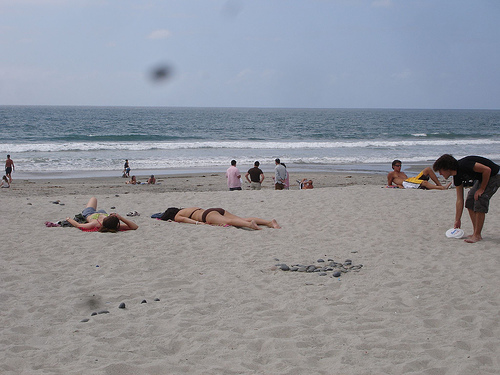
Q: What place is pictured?
A: It is a beach.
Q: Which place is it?
A: It is a beach.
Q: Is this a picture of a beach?
A: Yes, it is showing a beach.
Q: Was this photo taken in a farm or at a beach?
A: It was taken at a beach.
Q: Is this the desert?
A: No, it is the beach.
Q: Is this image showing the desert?
A: No, the picture is showing the beach.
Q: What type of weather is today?
A: It is clear.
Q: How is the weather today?
A: It is clear.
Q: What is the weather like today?
A: It is clear.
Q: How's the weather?
A: It is clear.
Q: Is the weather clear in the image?
A: Yes, it is clear.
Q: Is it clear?
A: Yes, it is clear.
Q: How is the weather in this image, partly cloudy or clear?
A: It is clear.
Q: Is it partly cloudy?
A: No, it is clear.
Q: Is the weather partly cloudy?
A: No, it is clear.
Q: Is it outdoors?
A: Yes, it is outdoors.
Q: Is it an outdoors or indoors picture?
A: It is outdoors.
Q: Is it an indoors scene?
A: No, it is outdoors.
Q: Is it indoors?
A: No, it is outdoors.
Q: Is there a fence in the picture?
A: No, there are no fences.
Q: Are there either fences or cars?
A: No, there are no fences or cars.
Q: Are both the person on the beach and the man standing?
A: Yes, both the person and the man are standing.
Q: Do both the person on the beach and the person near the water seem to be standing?
A: Yes, both the person and the man are standing.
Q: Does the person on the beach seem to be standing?
A: Yes, the person is standing.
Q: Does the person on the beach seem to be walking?
A: No, the person is standing.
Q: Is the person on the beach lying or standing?
A: The person is standing.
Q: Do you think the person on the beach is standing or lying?
A: The person is standing.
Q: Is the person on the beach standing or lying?
A: The person is standing.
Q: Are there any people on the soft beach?
A: Yes, there is a person on the beach.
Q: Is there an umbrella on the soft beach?
A: No, there is a person on the beach.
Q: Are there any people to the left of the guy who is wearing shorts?
A: Yes, there is a person to the left of the guy.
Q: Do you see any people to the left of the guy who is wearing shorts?
A: Yes, there is a person to the left of the guy.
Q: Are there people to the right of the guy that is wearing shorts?
A: No, the person is to the left of the guy.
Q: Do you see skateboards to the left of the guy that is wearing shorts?
A: No, there is a person to the left of the guy.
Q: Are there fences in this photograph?
A: No, there are no fences.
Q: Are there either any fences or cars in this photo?
A: No, there are no fences or cars.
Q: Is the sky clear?
A: Yes, the sky is clear.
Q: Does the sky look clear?
A: Yes, the sky is clear.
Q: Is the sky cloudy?
A: No, the sky is clear.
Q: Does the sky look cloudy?
A: No, the sky is clear.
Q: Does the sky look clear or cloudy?
A: The sky is clear.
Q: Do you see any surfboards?
A: No, there are no surfboards.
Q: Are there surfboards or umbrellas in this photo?
A: No, there are no surfboards or umbrellas.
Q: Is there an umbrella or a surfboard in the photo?
A: No, there are no surfboards or umbrellas.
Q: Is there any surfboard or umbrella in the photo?
A: No, there are no surfboards or umbrellas.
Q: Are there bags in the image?
A: No, there are no bags.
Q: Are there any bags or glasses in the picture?
A: No, there are no bags or glasses.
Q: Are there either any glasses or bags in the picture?
A: No, there are no bags or glasses.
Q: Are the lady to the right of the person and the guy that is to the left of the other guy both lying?
A: Yes, both the lady and the guy are lying.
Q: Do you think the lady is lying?
A: Yes, the lady is lying.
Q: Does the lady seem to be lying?
A: Yes, the lady is lying.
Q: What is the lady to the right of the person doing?
A: The lady is lying.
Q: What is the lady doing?
A: The lady is lying.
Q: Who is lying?
A: The lady is lying.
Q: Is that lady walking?
A: No, the lady is lying.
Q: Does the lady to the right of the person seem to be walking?
A: No, the lady is lying.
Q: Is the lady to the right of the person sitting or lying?
A: The lady is lying.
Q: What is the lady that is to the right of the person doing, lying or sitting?
A: The lady is lying.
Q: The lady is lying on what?
A: The lady is lying on the beach.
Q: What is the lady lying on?
A: The lady is lying on the beach.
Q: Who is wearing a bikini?
A: The lady is wearing a bikini.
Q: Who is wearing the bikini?
A: The lady is wearing a bikini.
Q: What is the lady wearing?
A: The lady is wearing a bikini.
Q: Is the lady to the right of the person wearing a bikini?
A: Yes, the lady is wearing a bikini.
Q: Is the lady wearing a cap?
A: No, the lady is wearing a bikini.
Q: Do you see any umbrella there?
A: No, there are no umbrellas.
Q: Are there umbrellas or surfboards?
A: No, there are no umbrellas or surfboards.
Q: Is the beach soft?
A: Yes, the beach is soft.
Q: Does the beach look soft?
A: Yes, the beach is soft.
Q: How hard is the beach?
A: The beach is soft.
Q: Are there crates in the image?
A: No, there are no crates.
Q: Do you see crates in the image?
A: No, there are no crates.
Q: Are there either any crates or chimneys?
A: No, there are no crates or chimneys.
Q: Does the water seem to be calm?
A: Yes, the water is calm.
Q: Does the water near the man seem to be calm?
A: Yes, the water is calm.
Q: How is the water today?
A: The water is calm.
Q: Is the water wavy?
A: No, the water is calm.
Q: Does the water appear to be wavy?
A: No, the water is calm.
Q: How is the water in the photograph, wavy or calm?
A: The water is calm.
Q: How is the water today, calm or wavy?
A: The water is calm.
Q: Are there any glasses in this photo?
A: No, there are no glasses.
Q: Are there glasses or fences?
A: No, there are no glasses or fences.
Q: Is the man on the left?
A: Yes, the man is on the left of the image.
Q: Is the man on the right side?
A: No, the man is on the left of the image.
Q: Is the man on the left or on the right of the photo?
A: The man is on the left of the image.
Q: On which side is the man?
A: The man is on the left of the image.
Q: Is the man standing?
A: Yes, the man is standing.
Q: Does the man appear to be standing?
A: Yes, the man is standing.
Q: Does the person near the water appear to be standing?
A: Yes, the man is standing.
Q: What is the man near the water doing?
A: The man is standing.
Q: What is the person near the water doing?
A: The man is standing.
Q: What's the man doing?
A: The man is standing.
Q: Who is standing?
A: The man is standing.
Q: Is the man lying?
A: No, the man is standing.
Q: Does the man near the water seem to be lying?
A: No, the man is standing.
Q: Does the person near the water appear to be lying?
A: No, the man is standing.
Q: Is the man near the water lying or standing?
A: The man is standing.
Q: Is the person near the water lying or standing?
A: The man is standing.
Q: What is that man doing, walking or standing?
A: The man is standing.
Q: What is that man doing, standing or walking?
A: The man is standing.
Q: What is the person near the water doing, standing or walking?
A: The man is standing.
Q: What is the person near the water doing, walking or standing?
A: The man is standing.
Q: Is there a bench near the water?
A: No, there is a man near the water.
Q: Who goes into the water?
A: The man goes into the water.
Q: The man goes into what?
A: The man goes into the water.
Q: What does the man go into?
A: The man goes into the water.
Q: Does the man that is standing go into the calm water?
A: Yes, the man goes into the water.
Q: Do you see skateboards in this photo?
A: No, there are no skateboards.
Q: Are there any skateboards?
A: No, there are no skateboards.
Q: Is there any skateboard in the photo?
A: No, there are no skateboards.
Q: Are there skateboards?
A: No, there are no skateboards.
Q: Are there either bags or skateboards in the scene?
A: No, there are no skateboards or bags.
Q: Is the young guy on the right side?
A: Yes, the guy is on the right of the image.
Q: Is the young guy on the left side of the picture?
A: No, the guy is on the right of the image.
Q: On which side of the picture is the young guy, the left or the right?
A: The guy is on the right of the image.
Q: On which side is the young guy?
A: The guy is on the right of the image.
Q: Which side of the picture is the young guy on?
A: The guy is on the right of the image.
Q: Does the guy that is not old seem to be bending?
A: Yes, the guy is bending.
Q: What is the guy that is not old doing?
A: The guy is bending.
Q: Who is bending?
A: The guy is bending.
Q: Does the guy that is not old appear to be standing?
A: No, the guy is bending.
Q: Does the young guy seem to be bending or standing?
A: The guy is bending.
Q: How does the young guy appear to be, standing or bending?
A: The guy is bending.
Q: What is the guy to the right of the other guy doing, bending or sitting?
A: The guy is bending.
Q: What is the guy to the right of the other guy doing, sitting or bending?
A: The guy is bending.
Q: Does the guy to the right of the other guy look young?
A: Yes, the guy is young.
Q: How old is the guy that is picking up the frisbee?
A: The guy is young.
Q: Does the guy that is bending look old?
A: No, the guy is young.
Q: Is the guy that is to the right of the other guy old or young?
A: The guy is young.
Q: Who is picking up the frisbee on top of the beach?
A: The guy is picking up the frisbee.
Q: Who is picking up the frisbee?
A: The guy is picking up the frisbee.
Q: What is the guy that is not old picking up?
A: The guy is picking up the frisbee.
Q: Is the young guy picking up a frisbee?
A: Yes, the guy is picking up a frisbee.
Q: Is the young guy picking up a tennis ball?
A: No, the guy is picking up a frisbee.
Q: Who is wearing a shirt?
A: The guy is wearing a shirt.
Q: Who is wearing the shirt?
A: The guy is wearing a shirt.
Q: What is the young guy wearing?
A: The guy is wearing a shirt.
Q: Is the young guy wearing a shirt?
A: Yes, the guy is wearing a shirt.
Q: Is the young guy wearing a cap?
A: No, the guy is wearing a shirt.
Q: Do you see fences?
A: No, there are no fences.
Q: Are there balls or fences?
A: No, there are no fences or balls.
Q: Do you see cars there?
A: No, there are no cars.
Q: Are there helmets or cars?
A: No, there are no cars or helmets.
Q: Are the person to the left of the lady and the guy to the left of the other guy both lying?
A: Yes, both the person and the guy are lying.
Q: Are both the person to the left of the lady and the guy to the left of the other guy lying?
A: Yes, both the person and the guy are lying.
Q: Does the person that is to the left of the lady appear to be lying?
A: Yes, the person is lying.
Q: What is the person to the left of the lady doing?
A: The person is lying.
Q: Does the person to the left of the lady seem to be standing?
A: No, the person is lying.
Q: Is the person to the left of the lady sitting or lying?
A: The person is lying.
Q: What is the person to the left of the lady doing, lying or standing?
A: The person is lying.